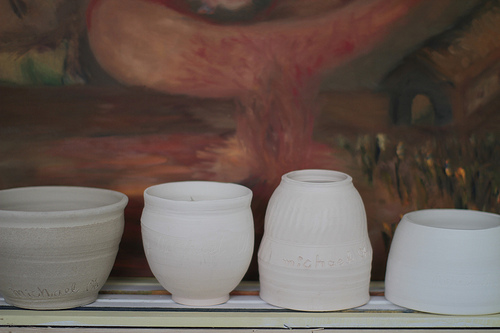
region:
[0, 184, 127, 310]
white ceramic bowl on very left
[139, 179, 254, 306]
white ceramic bowl second from left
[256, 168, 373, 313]
white ceramic fixture second from right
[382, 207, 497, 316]
white ceramic fixture on very right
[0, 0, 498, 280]
painting on wall behind ceramic pieces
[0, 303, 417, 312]
blue stripe on shelf in front of painting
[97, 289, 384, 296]
orange stripe on shelf in front of painting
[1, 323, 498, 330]
black stripe on front of shelf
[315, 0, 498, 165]
brown dwelling on right side of painting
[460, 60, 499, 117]
window on left side of dwelling in painting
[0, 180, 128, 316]
beige ceramic bowl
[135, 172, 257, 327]
white ceramic cup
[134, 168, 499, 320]
three white ceramic cups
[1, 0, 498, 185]
red painting in background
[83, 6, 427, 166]
"y" shaped figure in painting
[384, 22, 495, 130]
house in painting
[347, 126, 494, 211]
field of vegetation in painting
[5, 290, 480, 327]
fixture the bowls are standing on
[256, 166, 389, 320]
upside down ceramic cup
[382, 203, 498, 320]
upside down ceramic bowl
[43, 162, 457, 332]
the pots are white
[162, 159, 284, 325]
the pots are white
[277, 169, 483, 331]
the pots are white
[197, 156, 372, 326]
the pots are white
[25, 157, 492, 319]
the vases are made of ceramic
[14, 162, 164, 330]
the vases are made of ceramic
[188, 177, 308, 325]
the vases are made of ceramic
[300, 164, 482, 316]
the vases are made of ceramic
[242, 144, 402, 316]
the vases are made of ceramic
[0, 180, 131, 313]
a pot for outdoor planting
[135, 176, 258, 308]
a pot for outdoor planting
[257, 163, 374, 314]
several plastic pots for plants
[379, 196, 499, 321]
a pot for planting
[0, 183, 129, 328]
the darkest pot on the shelf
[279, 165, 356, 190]
circular bottom of the planter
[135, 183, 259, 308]
a molded white pot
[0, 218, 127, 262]
a ribbed set of circles on a pot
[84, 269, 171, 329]
stripes on the shelving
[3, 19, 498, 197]
a painting in the background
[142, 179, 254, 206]
Rim of white vase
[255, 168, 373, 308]
White ceramic vase with small opening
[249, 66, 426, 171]
Painting with multiple colors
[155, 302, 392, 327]
Table top under vases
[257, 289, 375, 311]
Base of white ceramic vase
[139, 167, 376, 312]
Two white vases beside each other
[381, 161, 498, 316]
White vase with painting behind it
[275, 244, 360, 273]
The name michael carved into the vase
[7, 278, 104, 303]
Name carved into the vase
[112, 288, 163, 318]
Yellow and white table top with blue stripe